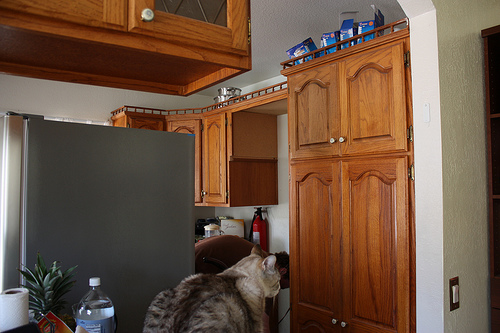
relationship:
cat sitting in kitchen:
[140, 245, 283, 331] [1, 4, 405, 329]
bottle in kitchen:
[72, 270, 117, 332] [1, 4, 405, 329]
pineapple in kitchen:
[15, 255, 82, 331] [0, 0, 499, 331]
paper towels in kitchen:
[0, 285, 30, 330] [0, 0, 499, 331]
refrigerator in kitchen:
[2, 87, 226, 328] [0, 0, 499, 331]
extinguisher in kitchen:
[251, 203, 267, 254] [0, 0, 499, 331]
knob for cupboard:
[140, 7, 155, 19] [0, 2, 249, 95]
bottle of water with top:
[72, 276, 117, 332] [85, 275, 103, 288]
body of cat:
[138, 267, 257, 331] [140, 245, 283, 331]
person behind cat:
[194, 232, 289, 288] [140, 245, 283, 331]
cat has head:
[140, 245, 283, 331] [237, 239, 286, 303]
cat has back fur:
[136, 226, 321, 331] [161, 269, 239, 330]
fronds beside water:
[10, 254, 84, 323] [69, 273, 118, 331]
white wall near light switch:
[439, 103, 490, 268] [414, 100, 431, 125]